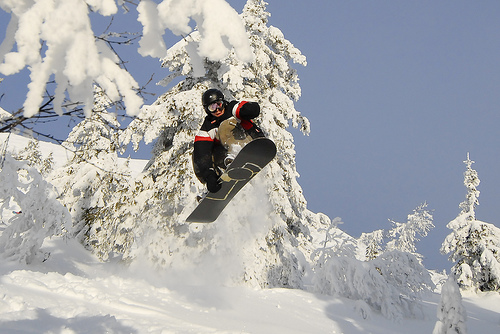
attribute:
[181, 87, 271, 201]
snowboarder — black, white, red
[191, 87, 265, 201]
man — black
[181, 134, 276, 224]
board — snow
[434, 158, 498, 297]
tree — tall, white, green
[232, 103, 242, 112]
trim — red, white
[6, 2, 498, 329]
day — bright, clear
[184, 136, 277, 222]
snowboard — black, yellow, white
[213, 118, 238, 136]
knee — bent